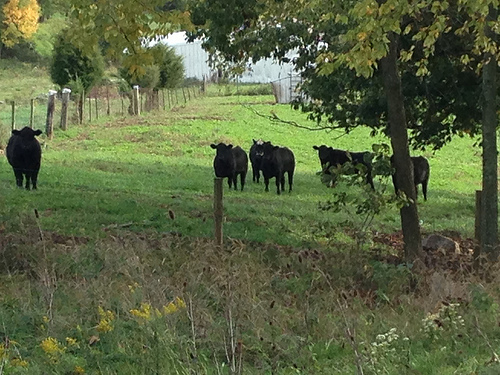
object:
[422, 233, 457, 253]
rock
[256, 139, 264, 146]
spot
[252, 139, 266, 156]
head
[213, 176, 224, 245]
fence post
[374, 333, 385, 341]
flowers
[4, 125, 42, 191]
cow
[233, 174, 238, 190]
leg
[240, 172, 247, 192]
leg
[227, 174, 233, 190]
leg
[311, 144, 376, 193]
cows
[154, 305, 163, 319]
flowers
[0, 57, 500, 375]
grass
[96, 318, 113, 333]
flowers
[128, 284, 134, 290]
flowers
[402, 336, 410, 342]
flowers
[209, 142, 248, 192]
cow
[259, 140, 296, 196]
cows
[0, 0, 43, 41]
tree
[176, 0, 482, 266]
tree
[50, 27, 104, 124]
tree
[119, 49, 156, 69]
tree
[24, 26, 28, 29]
leaf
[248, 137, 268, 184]
cows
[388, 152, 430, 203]
cows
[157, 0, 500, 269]
two trees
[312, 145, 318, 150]
ear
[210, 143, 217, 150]
ear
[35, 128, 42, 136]
ear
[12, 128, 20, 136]
ear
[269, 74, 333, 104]
fence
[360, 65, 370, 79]
leaves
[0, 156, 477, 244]
shaded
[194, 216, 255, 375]
plants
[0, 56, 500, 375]
field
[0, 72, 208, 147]
fence